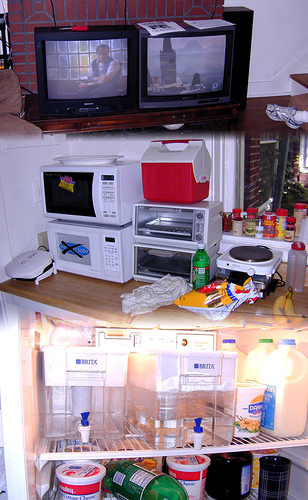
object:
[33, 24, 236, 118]
tvs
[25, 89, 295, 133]
shelf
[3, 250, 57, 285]
grill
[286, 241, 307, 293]
plastic bottle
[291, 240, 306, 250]
red lid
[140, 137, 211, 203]
cooler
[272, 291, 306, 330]
banana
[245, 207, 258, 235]
bottle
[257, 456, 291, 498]
mug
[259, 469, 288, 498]
design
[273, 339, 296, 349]
lid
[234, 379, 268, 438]
container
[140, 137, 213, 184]
lid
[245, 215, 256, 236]
oregano